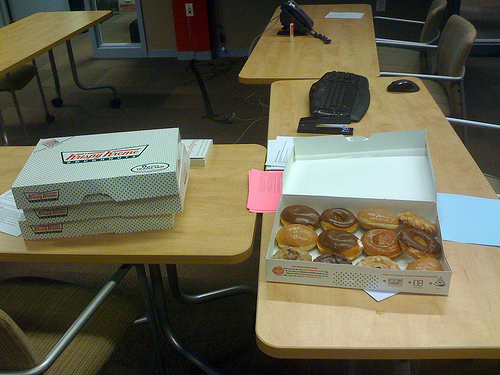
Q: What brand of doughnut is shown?
A: Krispy Kreme.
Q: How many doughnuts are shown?
A: 12.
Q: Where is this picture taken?
A: A classroom.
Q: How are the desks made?
A: Of wood.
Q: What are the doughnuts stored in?
A: Cardboard boxes.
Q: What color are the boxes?
A: White.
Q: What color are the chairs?
A: Brown.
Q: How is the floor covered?
A: With carpeting.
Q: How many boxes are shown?
A: Four.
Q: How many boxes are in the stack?
A: Three.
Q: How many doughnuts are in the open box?
A: A dozen.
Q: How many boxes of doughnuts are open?
A: One.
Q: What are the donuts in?
A: Box.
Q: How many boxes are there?
A: 4.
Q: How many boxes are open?
A: 1.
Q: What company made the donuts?
A: Krispy kreme.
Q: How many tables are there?
A: 4.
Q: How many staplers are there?
A: 1.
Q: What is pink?
A: Papers.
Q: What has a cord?
A: Phone.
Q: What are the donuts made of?
A: Wood.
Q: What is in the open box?
A: Donuts.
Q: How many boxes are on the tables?
A: Four.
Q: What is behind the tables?
A: Chairs.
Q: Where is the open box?
A: On the right.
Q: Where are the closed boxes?
A: On the left.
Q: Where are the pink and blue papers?
A: Under the lid of the open box.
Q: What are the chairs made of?
A: Metal.